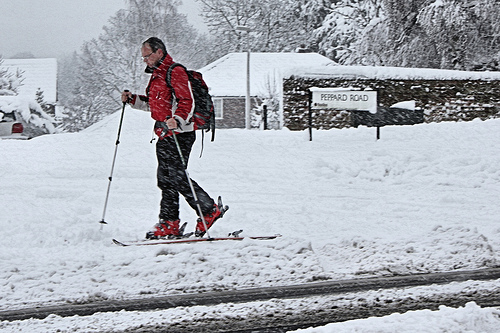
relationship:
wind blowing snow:
[33, 31, 114, 90] [111, 60, 144, 85]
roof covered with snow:
[175, 44, 335, 99] [3, 3, 498, 331]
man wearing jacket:
[120, 35, 229, 243] [129, 54, 201, 139]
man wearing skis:
[120, 35, 230, 240] [108, 232, 288, 247]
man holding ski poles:
[120, 35, 230, 240] [97, 89, 219, 238]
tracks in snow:
[68, 245, 496, 330] [279, 190, 436, 220]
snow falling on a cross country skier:
[2, 47, 499, 331] [118, 34, 230, 234]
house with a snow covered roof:
[209, 41, 440, 149] [198, 37, 360, 77]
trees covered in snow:
[47, 3, 479, 97] [5, 47, 495, 262]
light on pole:
[235, 25, 250, 32] [245, 30, 251, 128]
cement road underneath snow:
[2, 265, 494, 330] [0, 129, 485, 314]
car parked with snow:
[1, 94, 61, 142] [2, 95, 62, 132]